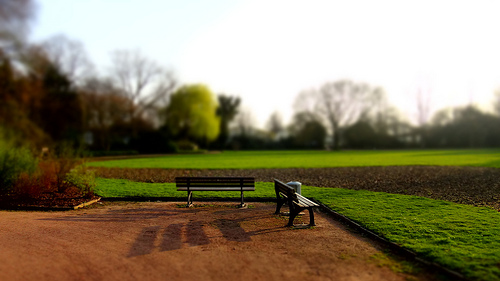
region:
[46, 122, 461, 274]
A large area with benches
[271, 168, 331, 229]
A brown bench facing the right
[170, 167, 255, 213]
A brown bench facing the left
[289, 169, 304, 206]
A trash can by bench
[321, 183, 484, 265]
A green area of grass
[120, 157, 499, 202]
A plowed line of soil around grass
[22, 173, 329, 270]
A dirt area with benches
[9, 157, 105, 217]
A group of shrubs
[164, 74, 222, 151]
A tree with light colored leaves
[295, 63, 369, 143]
A large tree in background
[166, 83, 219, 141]
a lush green tree in the distance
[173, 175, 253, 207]
a wooden bench facing north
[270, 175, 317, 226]
a wooden bench facing east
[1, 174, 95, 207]
a bed of red bushes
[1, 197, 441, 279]
dirt surrounded by green grass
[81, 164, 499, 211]
a dirt path surrounded by green grass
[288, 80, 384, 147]
a tree without foliage in the distance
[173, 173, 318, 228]
two park benches made out of wood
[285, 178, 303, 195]
a garbage can next to a bench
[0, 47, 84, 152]
colorful trees in the distance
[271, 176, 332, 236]
the bench beside the grass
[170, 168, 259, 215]
the bench beside the grass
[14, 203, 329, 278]
dirt behind the bench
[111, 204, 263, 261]
the shadow of the bench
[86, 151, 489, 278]
the grass is trimmed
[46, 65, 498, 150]
trees beside the grass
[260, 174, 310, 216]
the bench is wooden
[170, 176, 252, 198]
the bench is wooden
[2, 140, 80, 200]
bushes beside the benches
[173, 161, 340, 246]
the benches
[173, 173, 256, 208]
A brown park bench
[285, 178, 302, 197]
A silver garbage can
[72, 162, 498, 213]
A cleared brown field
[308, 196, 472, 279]
A piece of wooden landscape edge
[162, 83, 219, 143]
A light green tree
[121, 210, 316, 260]
The shadow of a park bench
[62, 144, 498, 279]
An open green field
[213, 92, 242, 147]
A dark green tree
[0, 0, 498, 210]
A wooded area in a park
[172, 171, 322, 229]
Two brown park benches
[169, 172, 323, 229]
two park benches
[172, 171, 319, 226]
two park benches in a park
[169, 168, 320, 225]
two park benches in dirt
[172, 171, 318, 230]
two park benches near some grass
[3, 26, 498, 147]
trees near a park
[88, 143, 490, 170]
grass in a park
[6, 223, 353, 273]
dirt patch in a park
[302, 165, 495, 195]
dirt patch in a park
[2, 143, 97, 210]
bushes in a park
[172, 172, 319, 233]
benches in a park